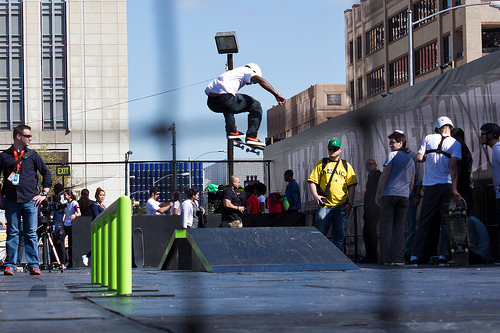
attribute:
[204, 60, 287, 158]
skateboarder — airborne, in the air, jumping, performing trick, skateboarding, flying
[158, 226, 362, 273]
skateboard ramp — black, wooden, two-sided, green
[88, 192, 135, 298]
railing — green, light green, metal, bright green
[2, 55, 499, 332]
skateboard park — urban, crowded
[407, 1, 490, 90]
light post — metal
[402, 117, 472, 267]
skateboarder — standing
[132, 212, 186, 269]
wall — black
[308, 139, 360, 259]
man — watching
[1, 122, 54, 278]
man — watching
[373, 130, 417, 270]
man — watching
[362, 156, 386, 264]
man — watching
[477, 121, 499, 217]
man — watching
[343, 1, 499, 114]
building — concrete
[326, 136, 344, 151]
hat — green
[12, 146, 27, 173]
lanyard — red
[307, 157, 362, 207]
shirt — yellow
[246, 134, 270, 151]
shoe — black, nike, red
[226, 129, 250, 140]
shoe — nike, black, red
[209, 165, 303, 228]
people — grouped, standing around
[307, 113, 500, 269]
people — grouped, standing around, watching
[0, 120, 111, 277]
people — grouped, standing around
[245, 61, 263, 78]
helmet — white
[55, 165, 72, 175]
exit sign — black, yellow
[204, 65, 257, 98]
shirt — white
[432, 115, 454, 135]
helmet — white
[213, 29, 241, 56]
arena light — large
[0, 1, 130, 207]
building — white, tall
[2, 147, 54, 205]
shirt — blue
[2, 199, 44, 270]
jeans — blue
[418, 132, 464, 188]
shirt — white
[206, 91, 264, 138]
jeans — blue